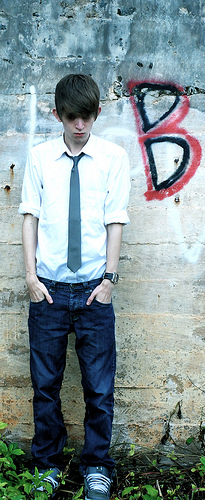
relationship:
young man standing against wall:
[19, 74, 130, 500] [0, 0, 204, 499]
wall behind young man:
[0, 0, 204, 499] [19, 74, 130, 500]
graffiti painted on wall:
[126, 80, 202, 200] [0, 0, 204, 499]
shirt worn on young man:
[19, 132, 130, 283] [19, 74, 130, 500]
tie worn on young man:
[65, 153, 85, 274] [19, 74, 130, 500]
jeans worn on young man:
[28, 277, 116, 470] [19, 74, 130, 500]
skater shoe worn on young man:
[31, 468, 64, 500] [19, 74, 130, 500]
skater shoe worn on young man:
[81, 465, 111, 500] [19, 74, 130, 500]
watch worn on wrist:
[101, 272, 120, 285] [104, 269, 121, 285]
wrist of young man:
[104, 269, 121, 285] [19, 74, 130, 500]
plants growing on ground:
[0, 440, 54, 499] [1, 457, 204, 499]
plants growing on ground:
[122, 483, 160, 499] [1, 457, 204, 499]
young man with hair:
[19, 74, 130, 500] [54, 74, 100, 122]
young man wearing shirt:
[19, 74, 130, 500] [19, 132, 130, 283]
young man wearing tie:
[19, 74, 130, 500] [65, 153, 85, 274]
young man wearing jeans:
[19, 74, 130, 500] [28, 277, 116, 470]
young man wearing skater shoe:
[19, 74, 130, 500] [31, 468, 64, 500]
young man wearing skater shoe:
[19, 74, 130, 500] [81, 465, 111, 500]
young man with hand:
[19, 74, 130, 500] [25, 279, 54, 304]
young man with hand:
[19, 74, 130, 500] [86, 279, 116, 306]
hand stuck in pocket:
[25, 279, 54, 304] [28, 291, 51, 327]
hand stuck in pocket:
[86, 279, 116, 306] [87, 290, 115, 334]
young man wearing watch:
[19, 74, 130, 500] [101, 272, 120, 285]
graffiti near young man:
[126, 80, 202, 200] [19, 74, 130, 500]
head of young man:
[54, 75, 99, 146] [19, 74, 130, 500]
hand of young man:
[25, 279, 54, 304] [19, 74, 130, 500]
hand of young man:
[86, 279, 116, 306] [19, 74, 130, 500]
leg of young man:
[28, 320, 67, 470] [19, 74, 130, 500]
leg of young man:
[79, 320, 115, 468] [19, 74, 130, 500]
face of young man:
[61, 114, 93, 143] [19, 74, 130, 500]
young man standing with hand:
[19, 74, 130, 500] [25, 279, 54, 304]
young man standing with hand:
[19, 74, 130, 500] [86, 279, 116, 306]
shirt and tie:
[19, 132, 130, 283] [65, 153, 85, 274]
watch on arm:
[101, 272, 120, 285] [103, 149, 129, 283]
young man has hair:
[19, 74, 130, 500] [54, 74, 100, 122]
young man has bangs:
[19, 74, 130, 500] [61, 90, 95, 115]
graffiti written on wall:
[126, 80, 202, 200] [0, 0, 204, 499]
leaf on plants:
[120, 486, 135, 496] [122, 483, 160, 499]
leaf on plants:
[143, 485, 159, 499] [122, 483, 160, 499]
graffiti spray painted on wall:
[126, 80, 202, 200] [0, 0, 204, 499]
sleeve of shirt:
[20, 150, 44, 219] [19, 132, 130, 283]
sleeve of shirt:
[103, 143, 131, 226] [19, 132, 130, 283]